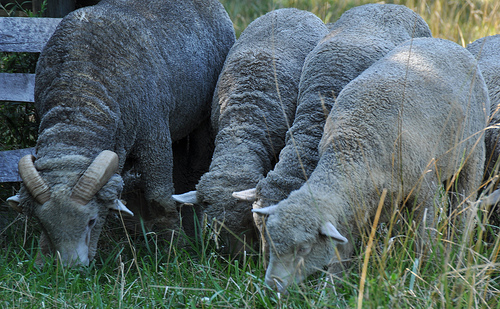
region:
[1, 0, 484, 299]
goats are eating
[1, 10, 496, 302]
the goats are eating grass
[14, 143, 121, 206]
the goat has horns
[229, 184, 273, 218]
the goat's ear is white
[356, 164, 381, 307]
the grass blade is brown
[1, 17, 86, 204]
the fence is grey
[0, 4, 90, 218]
the fence is old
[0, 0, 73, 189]
the fence is behind the goats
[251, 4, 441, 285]
the grass blades are tall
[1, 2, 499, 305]
five sheep grazing on some grass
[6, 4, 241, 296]
a ram grazing on some grass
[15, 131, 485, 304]
tall grass being eaten by four sheep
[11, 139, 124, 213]
the antlers on a ram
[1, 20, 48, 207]
a wooden fence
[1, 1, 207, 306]
a ram eating grass in front of a wooden fence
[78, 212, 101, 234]
the eye of a ram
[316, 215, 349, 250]
the ear of a sheep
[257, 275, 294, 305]
the nose of a sheep hidden by some grass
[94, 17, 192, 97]
the wool on a sheep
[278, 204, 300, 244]
part of a head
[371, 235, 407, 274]
part of a grass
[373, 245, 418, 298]
part of a grass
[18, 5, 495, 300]
three sheep and a ram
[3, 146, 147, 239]
two horns on rams head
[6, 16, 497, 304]
four animals eating together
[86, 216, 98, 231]
a black eye of ram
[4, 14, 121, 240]
wooden fence next to ram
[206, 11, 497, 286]
three sheep standing in grass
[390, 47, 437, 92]
reflection of sun on sheeps back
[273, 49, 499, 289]
one sheep is a lighter gray than the others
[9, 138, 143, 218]
horns on ram are brown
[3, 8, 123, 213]
three gray boards of a fence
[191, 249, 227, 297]
part of a grass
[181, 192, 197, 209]
edge of an ear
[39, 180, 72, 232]
head of a goat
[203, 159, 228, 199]
part of a sheep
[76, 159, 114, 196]
a horn on the animal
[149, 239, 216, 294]
the grass is tall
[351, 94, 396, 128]
the animals fur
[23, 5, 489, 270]
four sheep eating grass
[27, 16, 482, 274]
four sheep eating grass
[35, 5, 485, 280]
four sheep eating green grass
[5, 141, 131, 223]
the rams horns on his head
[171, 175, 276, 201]
ears on the sheep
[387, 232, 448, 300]
green grass in the yard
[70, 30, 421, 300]
four gray sheep eating grass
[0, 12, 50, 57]
wooden fence on the sheep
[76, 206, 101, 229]
rams right eye on his face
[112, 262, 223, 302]
more grass for the sheep